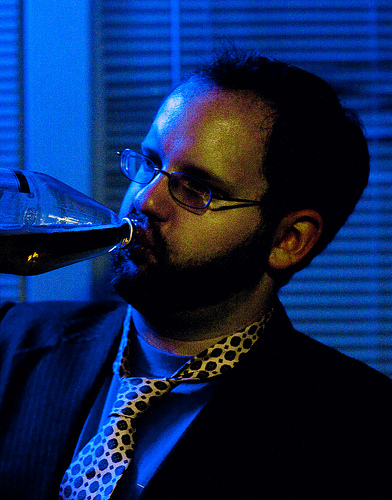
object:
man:
[0, 42, 372, 499]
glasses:
[117, 146, 262, 212]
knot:
[60, 300, 277, 496]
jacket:
[1, 279, 392, 499]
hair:
[304, 103, 363, 188]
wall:
[26, 3, 91, 166]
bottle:
[0, 167, 143, 279]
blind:
[98, 0, 391, 382]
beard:
[94, 219, 274, 312]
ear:
[266, 206, 324, 275]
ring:
[114, 217, 134, 253]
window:
[101, 2, 387, 363]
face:
[106, 78, 272, 292]